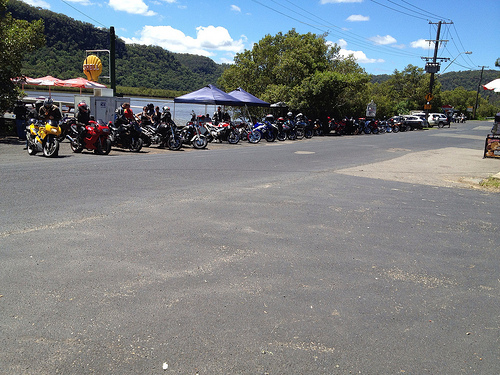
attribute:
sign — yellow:
[79, 54, 103, 78]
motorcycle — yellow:
[26, 121, 63, 155]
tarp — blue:
[170, 90, 244, 108]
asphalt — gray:
[374, 155, 479, 184]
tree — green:
[2, 13, 37, 56]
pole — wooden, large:
[108, 29, 121, 90]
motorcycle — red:
[72, 129, 112, 153]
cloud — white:
[199, 24, 225, 47]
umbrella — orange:
[59, 77, 88, 89]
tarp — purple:
[236, 90, 256, 107]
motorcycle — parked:
[149, 124, 177, 147]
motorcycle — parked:
[181, 126, 201, 143]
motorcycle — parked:
[207, 120, 228, 135]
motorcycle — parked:
[238, 125, 251, 139]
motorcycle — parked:
[278, 129, 288, 141]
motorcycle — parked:
[263, 127, 276, 142]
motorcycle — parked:
[289, 125, 301, 141]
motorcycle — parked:
[305, 127, 315, 139]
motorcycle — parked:
[328, 118, 347, 136]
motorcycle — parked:
[358, 123, 371, 132]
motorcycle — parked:
[379, 123, 387, 133]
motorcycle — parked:
[314, 123, 322, 133]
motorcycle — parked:
[342, 120, 359, 131]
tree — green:
[247, 43, 335, 94]